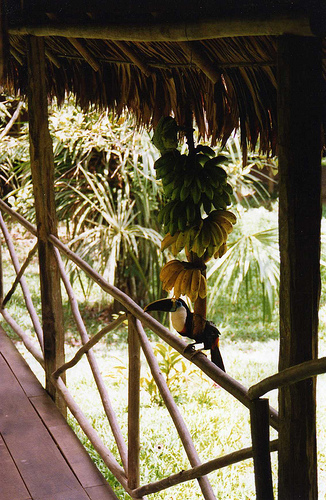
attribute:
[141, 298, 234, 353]
tucan — resting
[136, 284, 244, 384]
tropical bird — sitting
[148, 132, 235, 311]
bananas — yellow, bunches, hanging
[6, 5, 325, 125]
roofing — thatched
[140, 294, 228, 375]
toucan — resting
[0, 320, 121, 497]
planks — wooden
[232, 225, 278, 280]
palm tree — small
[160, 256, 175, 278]
banana — yellow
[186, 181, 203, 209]
banana — bunches, growing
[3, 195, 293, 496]
railing — wooden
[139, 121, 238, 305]
bananas — bunches